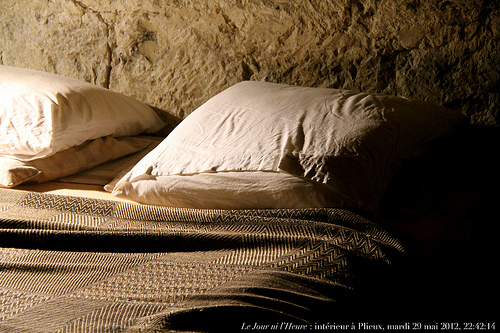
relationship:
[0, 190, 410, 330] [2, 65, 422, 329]
blanket on bed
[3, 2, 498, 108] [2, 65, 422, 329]
wall behind bed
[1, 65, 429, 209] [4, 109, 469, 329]
pillows on bed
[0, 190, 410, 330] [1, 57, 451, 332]
blanket on bed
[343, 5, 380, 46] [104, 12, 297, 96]
divot in wall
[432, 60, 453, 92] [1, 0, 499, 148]
divot in wall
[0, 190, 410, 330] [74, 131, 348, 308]
blanket on bed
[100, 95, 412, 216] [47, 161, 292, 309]
pillow on bed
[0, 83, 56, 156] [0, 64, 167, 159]
light on pillow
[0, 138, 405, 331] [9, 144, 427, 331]
blanket on bed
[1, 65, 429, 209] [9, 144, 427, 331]
pillows on bed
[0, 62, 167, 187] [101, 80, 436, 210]
pillow stacked on pillow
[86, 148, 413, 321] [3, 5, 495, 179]
divot in wall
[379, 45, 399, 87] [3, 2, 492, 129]
divot in wall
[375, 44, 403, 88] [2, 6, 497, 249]
divot in wall